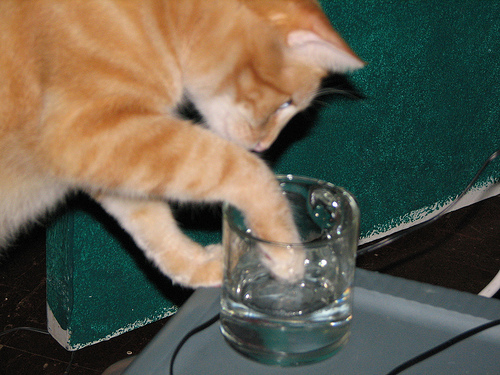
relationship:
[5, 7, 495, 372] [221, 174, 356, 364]
scene shows glass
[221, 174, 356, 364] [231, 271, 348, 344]
glass has water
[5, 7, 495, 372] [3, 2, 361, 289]
scene shows cat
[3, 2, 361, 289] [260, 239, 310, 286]
cat has paw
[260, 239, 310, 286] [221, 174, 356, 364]
paw in glass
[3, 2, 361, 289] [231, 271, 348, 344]
cat sticking paw into water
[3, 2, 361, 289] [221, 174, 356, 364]
cat sticking paw into glass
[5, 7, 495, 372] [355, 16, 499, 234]
scene shows wall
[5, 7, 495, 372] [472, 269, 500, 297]
scene shows power cord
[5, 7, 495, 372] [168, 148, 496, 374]
scene shows black power cord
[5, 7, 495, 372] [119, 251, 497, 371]
scene shows storage lid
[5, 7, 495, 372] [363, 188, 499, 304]
scene shows floor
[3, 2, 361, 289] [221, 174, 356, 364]
cat puts his paw into glass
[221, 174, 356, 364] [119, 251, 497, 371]
glass on top of storage lid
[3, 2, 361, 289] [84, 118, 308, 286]
cat has front legs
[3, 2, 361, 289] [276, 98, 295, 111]
cat has an eye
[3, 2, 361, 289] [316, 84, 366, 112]
cat has whiskers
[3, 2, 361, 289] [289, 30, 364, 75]
cat has an ear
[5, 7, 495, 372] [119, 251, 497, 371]
scene shows tub with a storage lid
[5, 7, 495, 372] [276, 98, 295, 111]
scene shows cat with an eye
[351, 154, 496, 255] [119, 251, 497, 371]
black power cord atop tub beneath storage lid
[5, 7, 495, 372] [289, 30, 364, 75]
scene shows cat with an ear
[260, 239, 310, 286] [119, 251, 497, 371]
paw in glass atop storage lid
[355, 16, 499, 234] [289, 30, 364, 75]
wall shows shadow of cat ear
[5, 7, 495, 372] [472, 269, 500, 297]
scene shows part of white power cord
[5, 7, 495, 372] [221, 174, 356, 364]
scene shows visible glass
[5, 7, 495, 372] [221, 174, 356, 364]
scene includes a visible glass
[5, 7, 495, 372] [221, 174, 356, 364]
scene shows a visible glass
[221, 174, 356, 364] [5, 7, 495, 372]
visible glass intrinsic to scene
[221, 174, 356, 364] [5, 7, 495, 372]
glass indpensable to scene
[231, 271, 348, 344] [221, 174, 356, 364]
water inside of glass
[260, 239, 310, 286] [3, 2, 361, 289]
paw belongs to cat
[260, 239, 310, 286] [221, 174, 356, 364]
paw inside of glass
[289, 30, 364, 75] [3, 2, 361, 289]
ear belongs to cat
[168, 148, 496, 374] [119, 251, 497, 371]
cord black that on storage lid